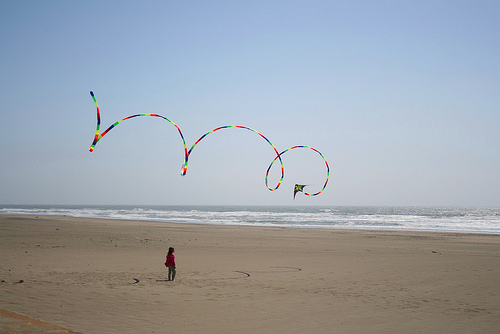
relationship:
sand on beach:
[0, 214, 500, 332] [7, 208, 359, 245]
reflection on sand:
[224, 263, 338, 280] [0, 214, 500, 332]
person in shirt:
[164, 246, 177, 281] [160, 241, 187, 268]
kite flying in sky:
[293, 184, 308, 201] [0, 1, 499, 205]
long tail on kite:
[88, 90, 332, 197] [71, 90, 365, 194]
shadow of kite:
[39, 261, 174, 306] [64, 71, 336, 207]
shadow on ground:
[39, 261, 174, 306] [9, 210, 498, 322]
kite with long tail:
[289, 177, 309, 202] [73, 71, 339, 217]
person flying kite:
[158, 242, 178, 284] [286, 178, 329, 201]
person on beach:
[158, 242, 178, 284] [248, 242, 423, 312]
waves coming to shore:
[134, 191, 499, 233] [11, 213, 498, 254]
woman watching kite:
[165, 246, 178, 282] [282, 174, 326, 203]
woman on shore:
[159, 239, 184, 284] [201, 234, 293, 280]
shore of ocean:
[201, 234, 293, 280] [354, 205, 459, 234]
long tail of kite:
[88, 90, 332, 197] [69, 80, 387, 227]